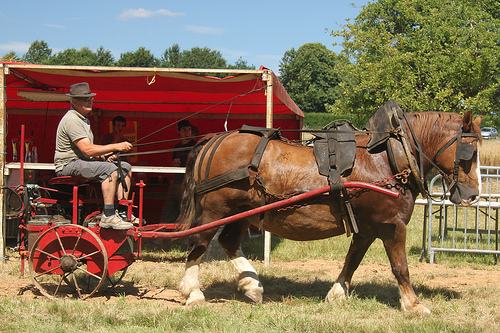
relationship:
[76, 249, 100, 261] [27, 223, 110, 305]
spoke supporting wheel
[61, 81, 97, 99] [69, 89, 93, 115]
top hat shading head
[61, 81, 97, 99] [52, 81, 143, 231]
top hat shading man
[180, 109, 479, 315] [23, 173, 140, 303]
horse pulling cart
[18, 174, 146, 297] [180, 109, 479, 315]
cart pulled by horse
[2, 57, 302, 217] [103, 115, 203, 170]
tent providing shade for people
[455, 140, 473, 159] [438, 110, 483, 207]
blinder on head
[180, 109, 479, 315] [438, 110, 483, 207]
horse has head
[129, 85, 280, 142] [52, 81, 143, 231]
bull whip held by man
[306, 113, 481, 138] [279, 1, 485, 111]
hedge in front of trees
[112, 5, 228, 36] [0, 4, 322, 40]
clouds in sky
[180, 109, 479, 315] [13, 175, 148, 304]
horse pulling cart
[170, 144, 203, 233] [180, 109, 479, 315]
brown tail of horse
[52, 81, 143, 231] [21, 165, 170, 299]
man on carriage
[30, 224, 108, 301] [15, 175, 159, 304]
wheel of carriage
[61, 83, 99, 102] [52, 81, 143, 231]
top hat on man